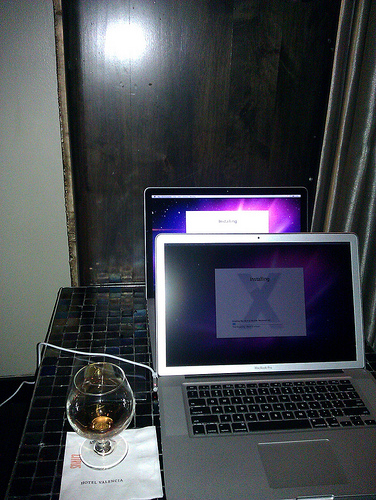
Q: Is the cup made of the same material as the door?
A: No, the cup is made of glass and the door is made of wood.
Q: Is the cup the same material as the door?
A: No, the cup is made of glass and the door is made of wood.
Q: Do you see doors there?
A: Yes, there is a door.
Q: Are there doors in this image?
A: Yes, there is a door.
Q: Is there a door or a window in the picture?
A: Yes, there is a door.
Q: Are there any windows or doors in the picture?
A: Yes, there is a door.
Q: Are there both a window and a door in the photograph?
A: No, there is a door but no windows.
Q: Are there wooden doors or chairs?
A: Yes, there is a wood door.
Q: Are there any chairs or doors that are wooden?
A: Yes, the door is wooden.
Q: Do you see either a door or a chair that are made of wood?
A: Yes, the door is made of wood.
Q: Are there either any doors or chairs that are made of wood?
A: Yes, the door is made of wood.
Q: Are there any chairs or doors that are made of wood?
A: Yes, the door is made of wood.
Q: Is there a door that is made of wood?
A: Yes, there is a door that is made of wood.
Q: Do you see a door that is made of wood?
A: Yes, there is a door that is made of wood.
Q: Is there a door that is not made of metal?
A: Yes, there is a door that is made of wood.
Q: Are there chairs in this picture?
A: No, there are no chairs.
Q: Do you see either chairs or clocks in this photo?
A: No, there are no chairs or clocks.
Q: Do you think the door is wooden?
A: Yes, the door is wooden.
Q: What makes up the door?
A: The door is made of wood.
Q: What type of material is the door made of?
A: The door is made of wood.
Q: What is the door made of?
A: The door is made of wood.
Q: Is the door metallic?
A: No, the door is wooden.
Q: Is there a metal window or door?
A: No, there is a door but it is wooden.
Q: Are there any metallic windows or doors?
A: No, there is a door but it is wooden.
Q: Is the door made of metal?
A: No, the door is made of wood.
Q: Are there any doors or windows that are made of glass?
A: No, there is a door but it is made of wood.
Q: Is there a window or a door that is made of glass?
A: No, there is a door but it is made of wood.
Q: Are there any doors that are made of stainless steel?
A: No, there is a door but it is made of wood.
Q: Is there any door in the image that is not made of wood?
A: No, there is a door but it is made of wood.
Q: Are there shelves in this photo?
A: No, there are no shelves.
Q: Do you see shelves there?
A: No, there are no shelves.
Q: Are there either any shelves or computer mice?
A: No, there are no shelves or computer mice.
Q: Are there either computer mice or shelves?
A: No, there are no shelves or computer mice.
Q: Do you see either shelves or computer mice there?
A: No, there are no shelves or computer mice.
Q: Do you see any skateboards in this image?
A: No, there are no skateboards.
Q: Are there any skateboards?
A: No, there are no skateboards.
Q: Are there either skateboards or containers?
A: No, there are no skateboards or containers.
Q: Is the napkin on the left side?
A: Yes, the napkin is on the left of the image.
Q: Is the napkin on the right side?
A: No, the napkin is on the left of the image.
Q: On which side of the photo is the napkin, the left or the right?
A: The napkin is on the left of the image.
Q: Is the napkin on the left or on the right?
A: The napkin is on the left of the image.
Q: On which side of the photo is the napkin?
A: The napkin is on the left of the image.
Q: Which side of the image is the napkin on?
A: The napkin is on the left of the image.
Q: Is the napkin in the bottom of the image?
A: Yes, the napkin is in the bottom of the image.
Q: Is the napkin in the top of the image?
A: No, the napkin is in the bottom of the image.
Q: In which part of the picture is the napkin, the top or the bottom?
A: The napkin is in the bottom of the image.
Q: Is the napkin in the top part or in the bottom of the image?
A: The napkin is in the bottom of the image.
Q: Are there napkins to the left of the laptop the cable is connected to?
A: Yes, there is a napkin to the left of the laptop.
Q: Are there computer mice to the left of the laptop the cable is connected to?
A: No, there is a napkin to the left of the laptop.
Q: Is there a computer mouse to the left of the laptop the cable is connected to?
A: No, there is a napkin to the left of the laptop.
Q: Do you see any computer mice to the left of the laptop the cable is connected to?
A: No, there is a napkin to the left of the laptop.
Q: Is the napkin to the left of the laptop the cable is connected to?
A: Yes, the napkin is to the left of the laptop.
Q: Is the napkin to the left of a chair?
A: No, the napkin is to the left of the laptop.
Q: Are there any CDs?
A: No, there are no cds.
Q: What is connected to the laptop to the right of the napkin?
A: The cable is connected to the laptop.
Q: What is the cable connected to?
A: The cable is connected to the laptop.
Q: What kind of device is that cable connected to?
A: The cable is connected to the laptop.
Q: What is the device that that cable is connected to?
A: The device is a laptop.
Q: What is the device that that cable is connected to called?
A: The device is a laptop.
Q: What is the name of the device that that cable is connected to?
A: The device is a laptop.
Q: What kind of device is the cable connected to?
A: The cable is connected to the laptop.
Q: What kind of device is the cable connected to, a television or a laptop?
A: The cable is connected to a laptop.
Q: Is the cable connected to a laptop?
A: Yes, the cable is connected to a laptop.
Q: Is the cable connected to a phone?
A: No, the cable is connected to a laptop.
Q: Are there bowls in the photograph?
A: No, there are no bowls.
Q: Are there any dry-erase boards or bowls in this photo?
A: No, there are no bowls or dry-erase boards.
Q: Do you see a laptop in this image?
A: Yes, there is a laptop.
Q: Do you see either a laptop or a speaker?
A: Yes, there is a laptop.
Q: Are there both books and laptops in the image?
A: No, there is a laptop but no books.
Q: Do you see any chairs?
A: No, there are no chairs.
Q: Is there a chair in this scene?
A: No, there are no chairs.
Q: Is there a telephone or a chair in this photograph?
A: No, there are no chairs or phones.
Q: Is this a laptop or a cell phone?
A: This is a laptop.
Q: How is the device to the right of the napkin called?
A: The device is a laptop.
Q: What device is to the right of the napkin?
A: The device is a laptop.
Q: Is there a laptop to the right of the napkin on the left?
A: Yes, there is a laptop to the right of the napkin.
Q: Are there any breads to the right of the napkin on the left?
A: No, there is a laptop to the right of the napkin.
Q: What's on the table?
A: The laptop is on the table.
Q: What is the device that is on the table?
A: The device is a laptop.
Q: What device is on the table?
A: The device is a laptop.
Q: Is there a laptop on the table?
A: Yes, there is a laptop on the table.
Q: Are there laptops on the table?
A: Yes, there is a laptop on the table.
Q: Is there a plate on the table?
A: No, there is a laptop on the table.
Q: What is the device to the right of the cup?
A: The device is a laptop.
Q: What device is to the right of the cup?
A: The device is a laptop.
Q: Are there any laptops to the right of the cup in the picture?
A: Yes, there is a laptop to the right of the cup.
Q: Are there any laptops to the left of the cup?
A: No, the laptop is to the right of the cup.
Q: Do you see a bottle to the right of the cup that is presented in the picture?
A: No, there is a laptop to the right of the cup.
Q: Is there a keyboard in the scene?
A: Yes, there is a keyboard.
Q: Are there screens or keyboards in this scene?
A: Yes, there is a keyboard.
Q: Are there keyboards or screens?
A: Yes, there is a keyboard.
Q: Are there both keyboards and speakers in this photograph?
A: No, there is a keyboard but no speakers.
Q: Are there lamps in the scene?
A: No, there are no lamps.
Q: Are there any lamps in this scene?
A: No, there are no lamps.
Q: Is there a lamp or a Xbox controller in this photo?
A: No, there are no lamps or Xbox controllers.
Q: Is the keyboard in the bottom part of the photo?
A: Yes, the keyboard is in the bottom of the image.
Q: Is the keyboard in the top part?
A: No, the keyboard is in the bottom of the image.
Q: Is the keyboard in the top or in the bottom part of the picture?
A: The keyboard is in the bottom of the image.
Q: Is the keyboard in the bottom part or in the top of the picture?
A: The keyboard is in the bottom of the image.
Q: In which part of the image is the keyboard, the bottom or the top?
A: The keyboard is in the bottom of the image.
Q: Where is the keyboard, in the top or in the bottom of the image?
A: The keyboard is in the bottom of the image.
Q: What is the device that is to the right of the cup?
A: The device is a keyboard.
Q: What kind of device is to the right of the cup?
A: The device is a keyboard.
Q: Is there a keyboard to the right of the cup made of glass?
A: Yes, there is a keyboard to the right of the cup.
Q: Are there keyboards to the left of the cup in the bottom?
A: No, the keyboard is to the right of the cup.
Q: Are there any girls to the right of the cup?
A: No, there is a keyboard to the right of the cup.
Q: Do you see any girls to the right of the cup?
A: No, there is a keyboard to the right of the cup.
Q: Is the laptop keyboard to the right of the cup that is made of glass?
A: Yes, the keyboard is to the right of the cup.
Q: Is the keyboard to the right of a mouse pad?
A: No, the keyboard is to the right of the cup.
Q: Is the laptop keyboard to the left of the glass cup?
A: No, the keyboard is to the right of the cup.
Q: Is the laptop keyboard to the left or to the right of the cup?
A: The keyboard is to the right of the cup.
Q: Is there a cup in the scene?
A: Yes, there is a cup.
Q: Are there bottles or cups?
A: Yes, there is a cup.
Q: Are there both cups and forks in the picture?
A: No, there is a cup but no forks.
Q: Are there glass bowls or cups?
A: Yes, there is a glass cup.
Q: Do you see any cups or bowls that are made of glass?
A: Yes, the cup is made of glass.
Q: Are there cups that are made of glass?
A: Yes, there is a cup that is made of glass.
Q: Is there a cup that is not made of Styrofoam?
A: Yes, there is a cup that is made of glass.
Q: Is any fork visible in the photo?
A: No, there are no forks.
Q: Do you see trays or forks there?
A: No, there are no forks or trays.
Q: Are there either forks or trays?
A: No, there are no forks or trays.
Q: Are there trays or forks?
A: No, there are no forks or trays.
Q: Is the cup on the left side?
A: Yes, the cup is on the left of the image.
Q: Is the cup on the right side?
A: No, the cup is on the left of the image.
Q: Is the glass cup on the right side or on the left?
A: The cup is on the left of the image.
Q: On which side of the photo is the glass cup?
A: The cup is on the left of the image.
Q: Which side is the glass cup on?
A: The cup is on the left of the image.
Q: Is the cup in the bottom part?
A: Yes, the cup is in the bottom of the image.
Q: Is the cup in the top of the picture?
A: No, the cup is in the bottom of the image.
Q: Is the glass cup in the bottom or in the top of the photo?
A: The cup is in the bottom of the image.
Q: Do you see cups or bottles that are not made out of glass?
A: No, there is a cup but it is made of glass.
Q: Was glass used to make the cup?
A: Yes, the cup is made of glass.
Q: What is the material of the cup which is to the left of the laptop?
A: The cup is made of glass.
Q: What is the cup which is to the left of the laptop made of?
A: The cup is made of glass.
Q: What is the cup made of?
A: The cup is made of glass.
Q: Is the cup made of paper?
A: No, the cup is made of glass.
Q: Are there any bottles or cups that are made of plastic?
A: No, there is a cup but it is made of glass.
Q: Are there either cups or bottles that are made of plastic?
A: No, there is a cup but it is made of glass.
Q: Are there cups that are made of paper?
A: No, there is a cup but it is made of glass.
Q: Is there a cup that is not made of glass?
A: No, there is a cup but it is made of glass.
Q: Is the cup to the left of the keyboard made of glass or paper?
A: The cup is made of glass.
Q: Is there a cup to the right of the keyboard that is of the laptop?
A: No, the cup is to the left of the keyboard.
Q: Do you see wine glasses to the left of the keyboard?
A: No, there is a cup to the left of the keyboard.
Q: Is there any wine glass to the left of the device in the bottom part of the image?
A: No, there is a cup to the left of the keyboard.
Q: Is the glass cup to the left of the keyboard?
A: Yes, the cup is to the left of the keyboard.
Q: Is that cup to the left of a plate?
A: No, the cup is to the left of the keyboard.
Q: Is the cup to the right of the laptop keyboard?
A: No, the cup is to the left of the keyboard.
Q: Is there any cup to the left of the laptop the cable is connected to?
A: Yes, there is a cup to the left of the laptop.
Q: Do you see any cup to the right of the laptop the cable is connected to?
A: No, the cup is to the left of the laptop.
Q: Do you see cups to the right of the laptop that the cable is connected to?
A: No, the cup is to the left of the laptop.